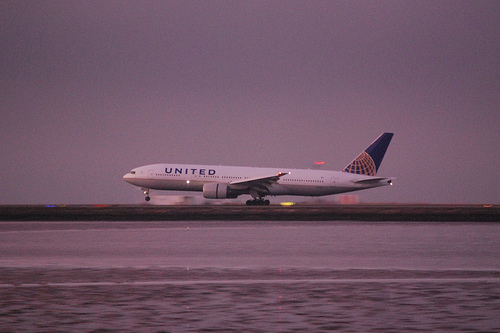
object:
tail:
[343, 131, 395, 176]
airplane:
[123, 130, 397, 207]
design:
[344, 152, 376, 176]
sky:
[0, 0, 500, 206]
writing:
[207, 169, 216, 176]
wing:
[229, 169, 290, 190]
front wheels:
[144, 196, 151, 201]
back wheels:
[245, 200, 253, 208]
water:
[0, 220, 500, 333]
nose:
[121, 170, 137, 184]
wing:
[351, 173, 386, 186]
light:
[278, 172, 281, 176]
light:
[288, 172, 291, 175]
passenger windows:
[156, 174, 158, 176]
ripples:
[0, 264, 499, 332]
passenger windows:
[282, 178, 285, 181]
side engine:
[201, 181, 243, 200]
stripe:
[214, 182, 220, 199]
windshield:
[128, 170, 136, 174]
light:
[389, 182, 394, 187]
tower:
[312, 158, 329, 205]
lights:
[313, 160, 323, 166]